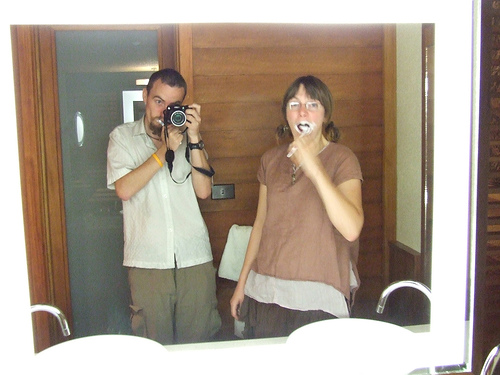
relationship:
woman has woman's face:
[233, 79, 367, 326] [282, 83, 327, 142]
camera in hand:
[78, 66, 242, 351] [182, 103, 205, 143]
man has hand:
[84, 69, 234, 349] [164, 121, 189, 146]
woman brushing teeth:
[233, 79, 367, 326] [299, 127, 309, 131]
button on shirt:
[164, 193, 169, 202] [102, 116, 217, 270]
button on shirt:
[165, 225, 173, 235] [102, 116, 217, 270]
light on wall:
[70, 110, 85, 147] [53, 69, 133, 331]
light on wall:
[70, 110, 85, 147] [178, 28, 392, 163]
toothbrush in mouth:
[287, 126, 309, 158] [292, 119, 311, 130]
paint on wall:
[59, 22, 166, 337] [52, 29, 182, 339]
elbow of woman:
[338, 208, 362, 243] [233, 79, 367, 326]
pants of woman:
[233, 285, 345, 335] [233, 79, 367, 326]